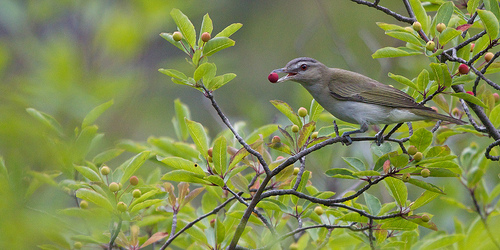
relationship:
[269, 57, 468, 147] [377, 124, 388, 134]
bird has leg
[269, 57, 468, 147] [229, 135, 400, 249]
bird sitting on branch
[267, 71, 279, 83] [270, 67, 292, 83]
berry inside of beak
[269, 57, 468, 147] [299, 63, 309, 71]
bird has eye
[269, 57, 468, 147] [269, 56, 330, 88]
bird has head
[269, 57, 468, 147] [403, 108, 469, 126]
bird has tail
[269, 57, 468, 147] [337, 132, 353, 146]
bird has foot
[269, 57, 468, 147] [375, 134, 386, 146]
bird has foot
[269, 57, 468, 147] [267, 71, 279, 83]
bird holding berry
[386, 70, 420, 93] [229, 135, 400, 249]
leaf on side of branch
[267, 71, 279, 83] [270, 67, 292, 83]
berry held in beak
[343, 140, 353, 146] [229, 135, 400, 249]
talon on top of branch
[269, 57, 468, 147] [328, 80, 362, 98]
bird has feather